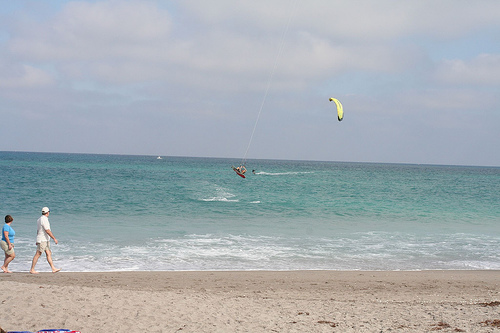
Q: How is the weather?
A: Sunny.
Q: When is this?
A: Daytime.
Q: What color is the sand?
A: Brown.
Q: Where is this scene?
A: At the beach.